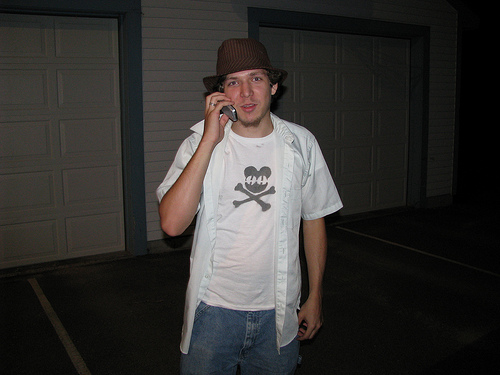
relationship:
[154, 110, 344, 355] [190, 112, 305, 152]
shirt has a collar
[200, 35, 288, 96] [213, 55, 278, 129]
hat on head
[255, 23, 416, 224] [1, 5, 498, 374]
door on garage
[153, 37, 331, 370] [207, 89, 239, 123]
boy holding phone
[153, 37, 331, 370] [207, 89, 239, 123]
man holding phone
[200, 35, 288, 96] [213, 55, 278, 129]
hat sitting on head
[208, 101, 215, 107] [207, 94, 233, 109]
ring on finger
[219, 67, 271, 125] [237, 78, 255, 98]
face has a nose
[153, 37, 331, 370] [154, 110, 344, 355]
man wearing a shirt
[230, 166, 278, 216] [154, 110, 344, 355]
design on shirt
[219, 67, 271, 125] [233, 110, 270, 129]
face has chin hair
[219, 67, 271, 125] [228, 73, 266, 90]
face has an eye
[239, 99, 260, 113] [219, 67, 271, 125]
mouth on face